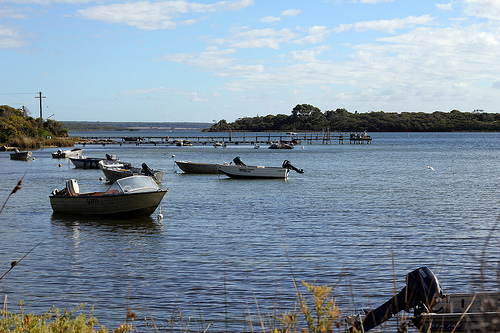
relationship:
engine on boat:
[47, 173, 81, 203] [40, 167, 180, 227]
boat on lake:
[48, 160, 168, 220] [0, 127, 500, 332]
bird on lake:
[421, 154, 441, 174] [0, 127, 500, 332]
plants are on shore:
[0, 273, 337, 330] [0, 276, 499, 331]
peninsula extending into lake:
[219, 103, 499, 139] [0, 127, 500, 332]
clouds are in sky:
[76, 3, 493, 132] [1, 1, 499, 122]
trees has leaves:
[278, 99, 380, 133] [295, 103, 361, 125]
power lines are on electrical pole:
[19, 90, 71, 127] [33, 87, 49, 139]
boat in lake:
[40, 167, 180, 227] [0, 127, 500, 332]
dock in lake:
[58, 126, 384, 152] [0, 127, 500, 332]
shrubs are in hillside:
[1, 105, 62, 138] [1, 98, 71, 148]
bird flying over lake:
[421, 154, 441, 174] [0, 127, 500, 332]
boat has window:
[40, 167, 180, 227] [125, 171, 156, 201]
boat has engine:
[40, 167, 180, 227] [58, 173, 82, 197]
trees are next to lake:
[217, 99, 498, 130] [0, 127, 500, 332]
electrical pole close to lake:
[33, 87, 49, 139] [0, 127, 500, 332]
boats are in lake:
[46, 146, 307, 229] [0, 127, 500, 332]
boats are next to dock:
[265, 134, 308, 156] [58, 126, 384, 152]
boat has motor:
[201, 149, 305, 189] [276, 157, 308, 178]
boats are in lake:
[2, 135, 306, 225] [0, 127, 500, 332]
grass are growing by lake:
[242, 283, 364, 331] [0, 127, 500, 332]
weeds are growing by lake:
[2, 272, 362, 331] [0, 127, 500, 332]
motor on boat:
[276, 157, 308, 178] [217, 149, 307, 184]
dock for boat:
[58, 126, 381, 147] [10, 139, 311, 225]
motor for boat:
[351, 266, 443, 331] [358, 263, 498, 331]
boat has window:
[40, 167, 180, 227] [113, 171, 165, 201]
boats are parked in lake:
[9, 127, 308, 228] [0, 127, 500, 332]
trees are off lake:
[203, 99, 497, 139] [0, 127, 500, 332]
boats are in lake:
[9, 127, 308, 228] [6, 121, 493, 326]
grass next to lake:
[242, 260, 373, 331] [6, 121, 493, 326]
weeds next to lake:
[3, 306, 184, 331] [6, 121, 493, 326]